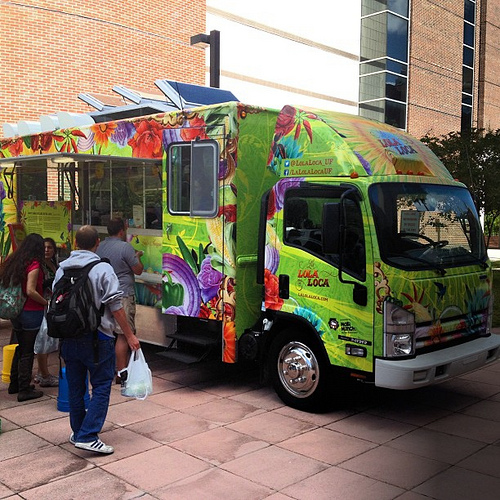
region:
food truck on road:
[18, 105, 459, 430]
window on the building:
[368, 18, 408, 63]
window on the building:
[380, 106, 400, 123]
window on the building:
[462, 68, 476, 90]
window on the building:
[462, 50, 474, 62]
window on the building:
[462, 94, 469, 104]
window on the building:
[459, 20, 476, 45]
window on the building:
[462, 1, 473, 25]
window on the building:
[463, 4, 475, 17]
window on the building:
[461, 105, 473, 138]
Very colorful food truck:
[3, 78, 499, 456]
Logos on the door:
[275, 240, 369, 341]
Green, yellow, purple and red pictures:
[147, 223, 247, 364]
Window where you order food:
[0, 129, 183, 255]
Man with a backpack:
[33, 213, 166, 459]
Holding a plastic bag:
[83, 266, 163, 426]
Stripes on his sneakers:
[67, 424, 121, 466]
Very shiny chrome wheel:
[268, 330, 328, 405]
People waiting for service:
[12, 212, 175, 462]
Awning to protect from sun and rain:
[1, 143, 160, 178]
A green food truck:
[5, 75, 495, 387]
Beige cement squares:
[151, 405, 321, 499]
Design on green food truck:
[166, 236, 230, 313]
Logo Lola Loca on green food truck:
[289, 258, 338, 294]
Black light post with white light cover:
[186, 25, 224, 79]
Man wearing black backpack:
[43, 268, 113, 337]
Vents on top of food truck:
[74, 77, 246, 112]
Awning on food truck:
[3, 147, 160, 224]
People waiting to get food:
[3, 215, 179, 418]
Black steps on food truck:
[154, 316, 226, 378]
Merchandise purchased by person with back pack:
[124, 350, 150, 402]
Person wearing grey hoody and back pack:
[39, 234, 131, 454]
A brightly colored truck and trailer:
[6, 118, 483, 378]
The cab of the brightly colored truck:
[279, 103, 492, 408]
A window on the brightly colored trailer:
[156, 137, 222, 224]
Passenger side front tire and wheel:
[261, 319, 338, 404]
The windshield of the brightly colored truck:
[370, 175, 492, 270]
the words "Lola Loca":
[296, 265, 333, 291]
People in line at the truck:
[4, 226, 147, 384]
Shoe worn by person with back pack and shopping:
[74, 433, 110, 454]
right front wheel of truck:
[270, 332, 332, 416]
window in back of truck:
[158, 146, 223, 220]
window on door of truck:
[275, 180, 374, 280]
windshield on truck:
[369, 179, 498, 274]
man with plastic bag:
[40, 229, 157, 451]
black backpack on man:
[48, 259, 113, 342]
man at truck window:
[72, 208, 154, 335]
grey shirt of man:
[97, 234, 140, 286]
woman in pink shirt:
[4, 235, 45, 406]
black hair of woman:
[2, 232, 39, 284]